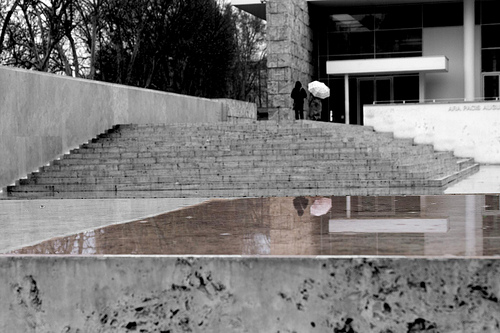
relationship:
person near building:
[291, 81, 307, 122] [228, 2, 499, 117]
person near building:
[306, 80, 327, 119] [228, 2, 499, 117]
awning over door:
[326, 55, 451, 74] [357, 76, 399, 124]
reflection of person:
[288, 196, 314, 229] [291, 81, 307, 122]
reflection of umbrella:
[309, 195, 335, 218] [306, 78, 334, 100]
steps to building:
[6, 117, 485, 198] [228, 2, 499, 117]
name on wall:
[448, 102, 500, 112] [360, 101, 500, 165]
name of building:
[448, 102, 500, 112] [228, 2, 499, 117]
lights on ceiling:
[331, 2, 373, 13] [326, 10, 425, 49]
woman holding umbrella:
[306, 80, 327, 119] [306, 78, 334, 100]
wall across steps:
[2, 63, 227, 194] [6, 117, 485, 198]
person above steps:
[291, 81, 307, 122] [6, 117, 485, 198]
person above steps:
[306, 80, 327, 119] [6, 117, 485, 198]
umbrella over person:
[306, 78, 334, 100] [306, 80, 327, 119]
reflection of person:
[309, 195, 335, 218] [306, 80, 327, 119]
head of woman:
[294, 79, 304, 88] [291, 81, 307, 122]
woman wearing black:
[291, 81, 307, 122] [299, 100, 300, 101]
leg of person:
[299, 107, 306, 117] [291, 81, 307, 122]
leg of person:
[295, 109, 300, 120] [291, 81, 307, 122]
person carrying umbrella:
[306, 80, 327, 119] [306, 78, 334, 100]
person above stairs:
[291, 81, 307, 122] [6, 117, 485, 198]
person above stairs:
[306, 80, 327, 119] [6, 117, 485, 198]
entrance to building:
[357, 76, 399, 124] [228, 2, 499, 117]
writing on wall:
[448, 102, 500, 112] [360, 101, 500, 165]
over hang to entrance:
[326, 55, 451, 74] [357, 76, 399, 124]